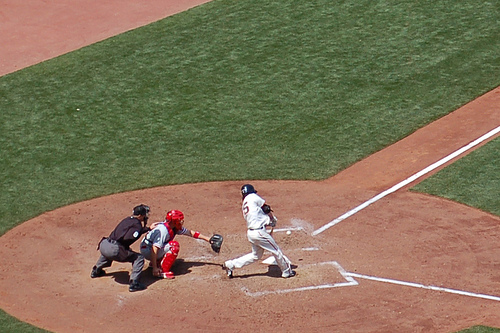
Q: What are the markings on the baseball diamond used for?
A: Guides.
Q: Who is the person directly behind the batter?
A: Catcher.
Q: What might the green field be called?
A: Turf.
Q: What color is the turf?
A: Green.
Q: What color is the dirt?
A: Brown.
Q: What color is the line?
A: White.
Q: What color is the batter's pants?
A: White.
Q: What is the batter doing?
A: Batting.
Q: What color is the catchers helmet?
A: Red.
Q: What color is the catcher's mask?
A: Red.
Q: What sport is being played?
A: Baseball.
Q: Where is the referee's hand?
A: On the catcher.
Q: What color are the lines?
A: White.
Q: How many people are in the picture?
A: 3.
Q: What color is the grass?
A: Green.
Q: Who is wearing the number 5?
A: Batter.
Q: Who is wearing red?
A: Catcher.